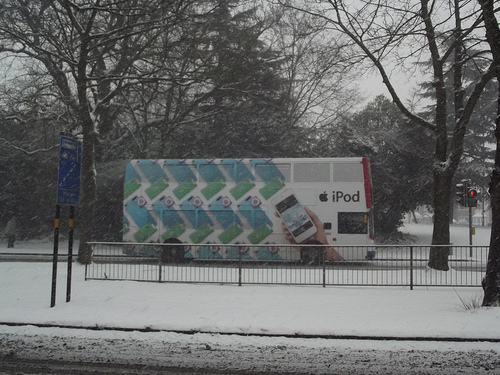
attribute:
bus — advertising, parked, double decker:
[117, 152, 396, 269]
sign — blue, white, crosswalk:
[52, 130, 83, 208]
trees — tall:
[32, 50, 193, 238]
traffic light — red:
[452, 181, 488, 259]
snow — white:
[200, 286, 457, 326]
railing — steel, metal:
[96, 241, 374, 253]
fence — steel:
[76, 230, 456, 296]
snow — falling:
[285, 35, 434, 138]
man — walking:
[4, 211, 15, 259]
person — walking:
[6, 202, 27, 256]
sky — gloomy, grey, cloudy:
[267, 30, 434, 95]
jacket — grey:
[7, 216, 15, 233]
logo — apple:
[315, 191, 330, 210]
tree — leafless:
[398, 54, 484, 266]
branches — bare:
[363, 35, 475, 123]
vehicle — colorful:
[122, 180, 380, 255]